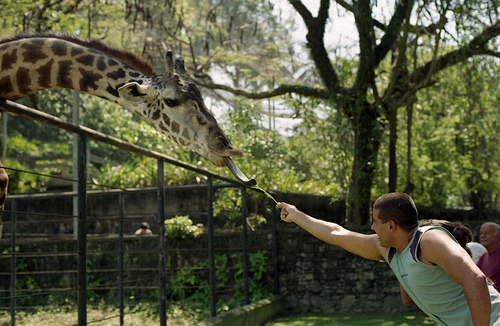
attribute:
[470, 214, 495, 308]
man — old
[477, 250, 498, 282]
shirt — magenta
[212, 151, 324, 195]
tongue — sticking out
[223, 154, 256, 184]
tongue — long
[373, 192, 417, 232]
hair — short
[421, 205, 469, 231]
backpack — brown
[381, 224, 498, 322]
tank top — grey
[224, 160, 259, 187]
tongue — long, black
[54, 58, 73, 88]
spot — dark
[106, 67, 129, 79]
spot — dark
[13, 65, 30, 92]
spot — dark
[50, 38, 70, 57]
spot — dark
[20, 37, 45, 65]
spot — dark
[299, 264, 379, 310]
brick wall — black, grey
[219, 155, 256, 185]
tongue — big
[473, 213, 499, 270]
gentleman — older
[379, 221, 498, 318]
shirt — green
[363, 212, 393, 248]
face — excited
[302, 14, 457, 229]
tree — beautiful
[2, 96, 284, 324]
fence — wire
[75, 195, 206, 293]
metal — fence, black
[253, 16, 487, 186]
trees — green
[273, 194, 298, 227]
hand — someone's 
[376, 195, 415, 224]
haircut — short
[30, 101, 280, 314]
cage — black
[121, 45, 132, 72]
mane — brown, short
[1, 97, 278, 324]
metal fence — black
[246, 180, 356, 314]
wall — stone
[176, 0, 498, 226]
tree — big, mossy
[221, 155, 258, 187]
tongue — black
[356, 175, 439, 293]
shirt — light colored, sleeveless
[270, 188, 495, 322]
man — excited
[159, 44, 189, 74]
horns — black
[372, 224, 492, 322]
shirt — pale green